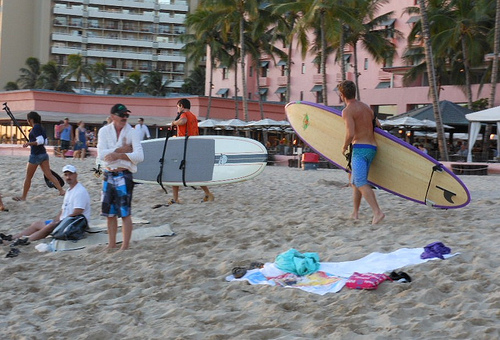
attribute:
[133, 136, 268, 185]
surfboard — gray, white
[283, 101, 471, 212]
surfboard — tan, purple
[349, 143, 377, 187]
swim trunks — blue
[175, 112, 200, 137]
shirt — orange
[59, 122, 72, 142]
shirt — blue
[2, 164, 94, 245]
man — sitting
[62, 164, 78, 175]
hat — white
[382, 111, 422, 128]
umbrella — white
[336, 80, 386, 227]
man — shirtless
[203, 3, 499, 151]
building — pink, large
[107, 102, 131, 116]
hat — black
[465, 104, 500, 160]
tent — white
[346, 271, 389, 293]
bag — pink, purple